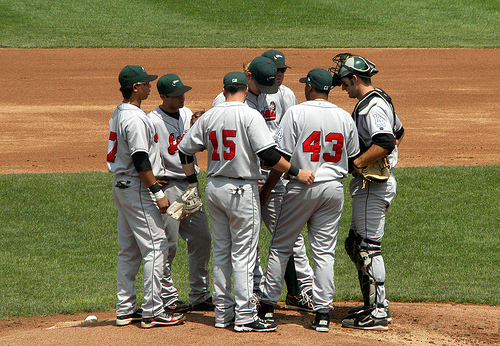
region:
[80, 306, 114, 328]
small white ball on the ground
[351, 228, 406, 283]
large knee pads around knee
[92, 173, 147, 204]
blue and white glove in man's back pocket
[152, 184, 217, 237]
white glove in man's hand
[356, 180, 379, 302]
line at side of player's pants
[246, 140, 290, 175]
black edge of under shirt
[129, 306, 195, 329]
black sneakers with red and white trim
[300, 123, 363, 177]
large red numbers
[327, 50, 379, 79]
blue and green helmet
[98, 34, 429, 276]
players congregating on field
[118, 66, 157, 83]
black baseball hat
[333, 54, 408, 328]
man in baseball catchers uniform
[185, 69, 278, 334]
man wearing baseball uniform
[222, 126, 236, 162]
red number fiveon shirt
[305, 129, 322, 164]
red number four on shirt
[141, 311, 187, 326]
grey white and orange baseball cleat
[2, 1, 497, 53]
green grass on baseball field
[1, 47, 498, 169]
brown dirt on baseball field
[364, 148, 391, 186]
brown leather catchers mitt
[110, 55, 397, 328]
men talkingon baseball field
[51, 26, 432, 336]
a group of baseball players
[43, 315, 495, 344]
brown dirt on a baseball field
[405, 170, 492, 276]
green grass on a ball field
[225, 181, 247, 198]
a white glove in the back pocket of a ball player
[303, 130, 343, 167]
the number 43 on the back of a jersey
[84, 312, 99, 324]
a white baseball on the ground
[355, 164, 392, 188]
a baseball glove in a player's left hand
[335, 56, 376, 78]
a green and gray helmet on the catcher's head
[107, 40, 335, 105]
green caps on the ballplayers' heads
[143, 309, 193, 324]
red black and white Nike sneakers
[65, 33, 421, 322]
group of guys in jersey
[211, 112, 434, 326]
group of guys in jersey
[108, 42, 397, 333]
a baseball team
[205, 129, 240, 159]
the number fifteen in red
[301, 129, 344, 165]
the number forty-three in red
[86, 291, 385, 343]
the pitchers mound on a baseball diamond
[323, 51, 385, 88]
a baseball catchers mask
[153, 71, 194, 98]
a black and white baseball cap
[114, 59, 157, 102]
a head of a man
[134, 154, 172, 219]
the arm of a man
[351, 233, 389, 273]
a knee pad on a knee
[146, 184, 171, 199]
a sweat band on a wrist